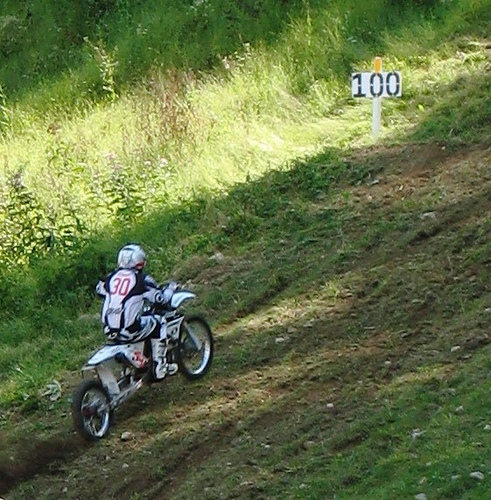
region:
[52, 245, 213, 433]
A person on a motorcycle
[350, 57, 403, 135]
A sign with 100 on it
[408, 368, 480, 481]
Rocks in a field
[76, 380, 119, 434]
A motorcycle tire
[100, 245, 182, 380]
A person in a protective suit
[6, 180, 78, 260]
Plants in a field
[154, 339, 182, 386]
The boot is silver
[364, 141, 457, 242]
Dirt and rocks in a field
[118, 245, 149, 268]
The helmet is grey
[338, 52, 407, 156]
A sign stands in the field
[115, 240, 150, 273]
The person is wearing a helmet.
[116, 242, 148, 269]
The helmet is white.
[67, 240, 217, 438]
The person is on a bike.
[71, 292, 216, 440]
The bike is white.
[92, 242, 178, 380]
The person is wearing a white outfit.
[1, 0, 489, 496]
The grass is green.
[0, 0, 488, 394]
The grass is tall.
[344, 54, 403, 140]
The sign is white.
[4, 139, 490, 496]
The ground is brown and green.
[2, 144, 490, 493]
The dirt is brown.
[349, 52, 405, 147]
A numbered marker on the track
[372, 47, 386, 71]
Yellow tip of truck marker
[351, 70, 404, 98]
Number 100 written on white wood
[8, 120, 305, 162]
Rays of the sun shining on the grass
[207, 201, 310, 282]
Shadow cast on the grass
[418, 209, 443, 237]
Piece of rock infront of rider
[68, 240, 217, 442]
A rider on his motorbike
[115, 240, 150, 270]
The motorcyclist with his helmet on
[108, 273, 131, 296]
Number 30 written on the back of suit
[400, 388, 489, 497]
Pieces of rock scattered on the grass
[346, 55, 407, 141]
white post with black numbers and yellow reflector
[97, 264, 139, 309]
number 30 on back of rider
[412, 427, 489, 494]
rocks laying in the grass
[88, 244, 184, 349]
person riding a motorcycle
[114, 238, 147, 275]
silver helmet on bike rider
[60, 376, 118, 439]
back tire of motorcycle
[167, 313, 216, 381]
front tire of the motorcycle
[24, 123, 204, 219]
tall weeds on the side of the trail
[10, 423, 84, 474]
dirt in the air from the tire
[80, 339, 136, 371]
white fender on motorcycle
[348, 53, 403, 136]
a white sign that says 100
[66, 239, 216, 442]
a rider on a dirtbike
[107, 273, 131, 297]
number on the rider's back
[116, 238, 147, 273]
a silver helmet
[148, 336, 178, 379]
a white boot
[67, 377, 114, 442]
back wheel of the dirtbike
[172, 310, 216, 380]
front wheel of the dirtbike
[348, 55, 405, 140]
sign indicating distance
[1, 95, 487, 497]
dirt path up the hill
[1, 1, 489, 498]
a grassy hill